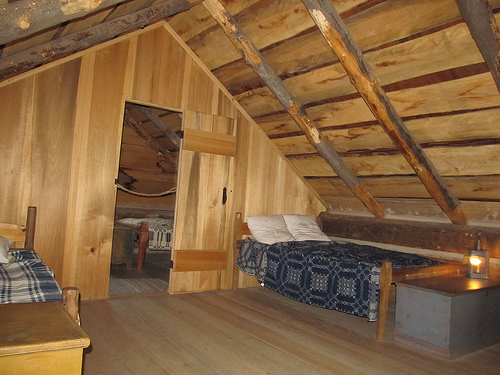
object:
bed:
[235, 211, 464, 341]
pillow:
[246, 214, 297, 245]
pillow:
[281, 213, 331, 242]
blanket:
[236, 237, 449, 322]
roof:
[1, 1, 500, 233]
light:
[467, 239, 489, 279]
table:
[393, 267, 500, 359]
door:
[167, 108, 244, 294]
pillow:
[0, 235, 15, 263]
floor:
[76, 257, 500, 374]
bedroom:
[107, 97, 183, 294]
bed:
[113, 214, 174, 273]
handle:
[222, 186, 228, 205]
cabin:
[1, 1, 499, 375]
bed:
[0, 235, 63, 307]